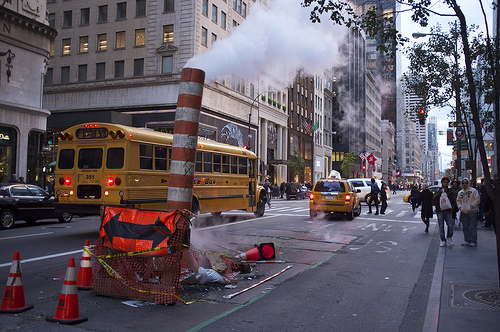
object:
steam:
[177, 0, 357, 84]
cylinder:
[165, 66, 207, 207]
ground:
[0, 177, 500, 332]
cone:
[60, 261, 84, 323]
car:
[304, 169, 362, 220]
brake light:
[106, 177, 114, 186]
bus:
[49, 120, 272, 227]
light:
[103, 190, 110, 197]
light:
[65, 179, 71, 183]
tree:
[295, 0, 499, 207]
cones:
[0, 250, 35, 314]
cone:
[48, 255, 93, 324]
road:
[0, 182, 500, 332]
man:
[430, 175, 462, 248]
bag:
[439, 188, 454, 210]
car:
[0, 182, 78, 230]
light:
[362, 166, 365, 170]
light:
[243, 144, 248, 149]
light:
[345, 195, 351, 200]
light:
[418, 108, 427, 115]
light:
[105, 178, 114, 186]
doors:
[247, 157, 256, 208]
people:
[453, 177, 481, 248]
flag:
[302, 117, 315, 133]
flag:
[358, 152, 366, 161]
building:
[44, 0, 293, 202]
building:
[397, 74, 433, 185]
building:
[0, 2, 56, 184]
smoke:
[184, 0, 364, 89]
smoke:
[189, 209, 233, 266]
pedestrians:
[366, 178, 381, 216]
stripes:
[51, 256, 81, 322]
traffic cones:
[233, 242, 276, 262]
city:
[0, 1, 499, 331]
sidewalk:
[433, 217, 500, 332]